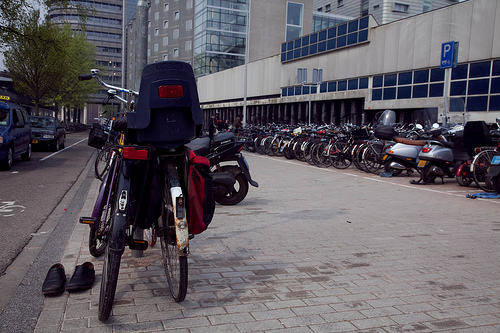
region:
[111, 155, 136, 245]
the fender is made of metal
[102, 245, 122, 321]
the tire is made of rubber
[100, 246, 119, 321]
the tire is black in color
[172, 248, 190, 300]
the tire is black in color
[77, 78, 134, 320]
the bicycle is parked on the street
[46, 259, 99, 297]
a pair of shoes are on the street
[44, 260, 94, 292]
the shoes are black in color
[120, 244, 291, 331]
a shadow is on the street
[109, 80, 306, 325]
the bicycle is casting a shadow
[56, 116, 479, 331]
the street is paved with bricks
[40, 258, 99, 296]
A pair of black shoes.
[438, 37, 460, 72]
A blue parking sign.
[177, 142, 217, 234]
A red and black bag.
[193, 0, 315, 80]
A brown and glass building.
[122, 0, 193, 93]
A mirrored glass building.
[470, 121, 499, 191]
A parked bicycle.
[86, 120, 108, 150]
A black bike basket.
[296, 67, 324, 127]
Gray metal street lights.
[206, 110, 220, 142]
A man dressed in black.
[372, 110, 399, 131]
A motorcycle windshield.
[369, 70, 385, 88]
The window is rectangular.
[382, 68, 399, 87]
The window is rectangular.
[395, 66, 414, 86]
The window is rectangular.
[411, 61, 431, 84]
The window is rectangular.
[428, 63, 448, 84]
The window is rectangular.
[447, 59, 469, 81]
The window is rectangular.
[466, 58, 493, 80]
The window is rectangular.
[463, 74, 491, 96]
The window is rectangular.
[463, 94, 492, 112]
The window is rectangular.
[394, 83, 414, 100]
The window is rectangular.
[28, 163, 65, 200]
The street is made of asphalt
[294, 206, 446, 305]
The ground is made of concrete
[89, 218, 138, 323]
The back tire of the bike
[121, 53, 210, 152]
The seat on the bike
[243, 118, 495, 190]
A row of different kind of bike's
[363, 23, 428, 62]
The building is the color grey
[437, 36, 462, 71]
The sign on the side of the building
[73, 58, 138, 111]
The handle on the back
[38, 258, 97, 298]
The shoes on the ground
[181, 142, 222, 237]
The backpack on the bike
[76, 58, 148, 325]
A purple and black bike.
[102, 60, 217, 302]
A bike with a baby seat.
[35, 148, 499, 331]
A paved brick road.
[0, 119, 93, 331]
A dark gray road.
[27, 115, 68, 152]
A dark colored car.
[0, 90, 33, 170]
A blue colored taxi.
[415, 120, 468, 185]
A small gray motorbike.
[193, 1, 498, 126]
A large white building.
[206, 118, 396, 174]
A row of bicycles.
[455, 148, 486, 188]
A small red motorbike.